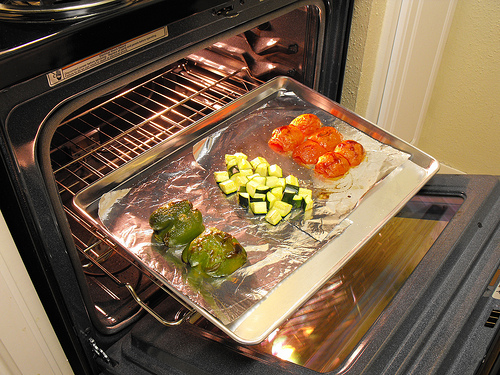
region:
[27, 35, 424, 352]
the oven is open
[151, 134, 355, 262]
the tray is silvery in color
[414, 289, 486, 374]
oven is bl;ack in color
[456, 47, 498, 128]
wall isdull yellow in color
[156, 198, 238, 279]
the fruits are baiikeed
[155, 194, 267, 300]
the fruits are green in color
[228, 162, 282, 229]
vegetables are green yellow in color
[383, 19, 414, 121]
wall frame is white in color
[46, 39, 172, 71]
words are written on a white paper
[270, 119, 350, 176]
food is red brown in color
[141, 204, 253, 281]
two green peppers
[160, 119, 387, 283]
three different foods on tray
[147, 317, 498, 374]
oven door is opened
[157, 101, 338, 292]
food on the tin foil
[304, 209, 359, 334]
tray is silver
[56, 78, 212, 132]
racks of oven that hold food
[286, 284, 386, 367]
glass on oven door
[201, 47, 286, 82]
light is on in oven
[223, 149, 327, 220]
chopped zucchini in the middle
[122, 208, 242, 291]
peppers are cooked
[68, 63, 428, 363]
the oven is open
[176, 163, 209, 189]
soilpaper is silver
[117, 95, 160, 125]
rack is made of metal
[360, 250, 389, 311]
glass is on the oven door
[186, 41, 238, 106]
light is in the oven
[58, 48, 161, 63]
sticker is on the oven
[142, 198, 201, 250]
the geen peper is cooked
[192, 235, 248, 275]
the green pepper is grilled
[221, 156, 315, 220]
the cucumber is green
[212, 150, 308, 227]
the cucumber is in small pieces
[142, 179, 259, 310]
grilled green peppers on metal tray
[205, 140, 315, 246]
grilled zucchni on metal pan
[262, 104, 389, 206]
grilled tomatoe on metal pan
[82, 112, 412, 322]
aluminium covering top of pan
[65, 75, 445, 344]
metal pan used in oven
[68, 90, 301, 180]
metal rack on top shlef of oven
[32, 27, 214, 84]
warning label inside oven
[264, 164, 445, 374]
glass window on oven door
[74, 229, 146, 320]
burner unit inside oven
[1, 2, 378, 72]
top of stove range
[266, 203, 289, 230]
this is a slice of gogget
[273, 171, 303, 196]
this is a slice of gogget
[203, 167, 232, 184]
this is a slice of gogget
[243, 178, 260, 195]
this is a slice of gogget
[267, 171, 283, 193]
this is a slice of gogget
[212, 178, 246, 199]
this is a slice of gogget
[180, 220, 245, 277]
this is a vegetable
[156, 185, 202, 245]
this is a vegetable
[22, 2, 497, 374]
this is an oven